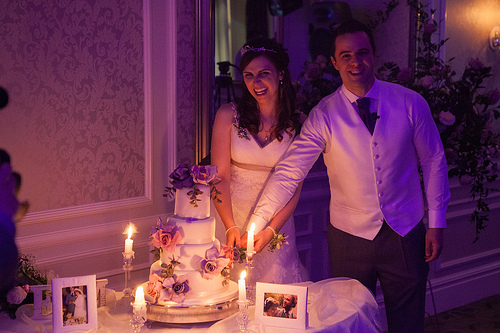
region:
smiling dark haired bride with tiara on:
[203, 30, 314, 290]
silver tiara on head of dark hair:
[234, 39, 289, 65]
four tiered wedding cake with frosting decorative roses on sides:
[127, 151, 244, 327]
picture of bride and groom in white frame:
[47, 269, 102, 331]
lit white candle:
[120, 218, 139, 252]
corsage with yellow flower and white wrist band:
[261, 220, 292, 255]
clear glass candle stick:
[111, 249, 138, 319]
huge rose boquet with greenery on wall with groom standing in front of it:
[299, 33, 499, 259]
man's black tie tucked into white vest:
[350, 92, 382, 137]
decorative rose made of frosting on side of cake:
[145, 213, 192, 257]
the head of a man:
[305, 20, 435, 90]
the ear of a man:
[315, 35, 352, 82]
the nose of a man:
[341, 50, 366, 75]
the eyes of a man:
[332, 26, 394, 77]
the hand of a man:
[403, 212, 452, 262]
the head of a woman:
[217, 28, 304, 116]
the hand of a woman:
[207, 210, 256, 250]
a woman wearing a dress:
[187, 0, 344, 275]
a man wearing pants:
[328, 189, 495, 299]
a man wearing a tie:
[336, 40, 437, 179]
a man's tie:
[355, 97, 375, 125]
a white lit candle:
[247, 223, 257, 252]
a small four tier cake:
[156, 172, 226, 293]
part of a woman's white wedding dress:
[222, 115, 303, 282]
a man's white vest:
[311, 83, 427, 240]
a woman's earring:
[280, 80, 285, 89]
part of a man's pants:
[320, 219, 434, 329]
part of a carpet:
[431, 296, 498, 328]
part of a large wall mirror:
[196, 0, 425, 174]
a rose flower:
[7, 283, 32, 307]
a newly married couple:
[98, 29, 498, 300]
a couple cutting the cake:
[146, 11, 347, 323]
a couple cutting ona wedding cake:
[122, 41, 409, 329]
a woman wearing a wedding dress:
[119, 43, 447, 329]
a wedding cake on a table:
[114, 141, 289, 331]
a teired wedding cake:
[121, 130, 196, 328]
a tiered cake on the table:
[128, 152, 303, 319]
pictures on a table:
[41, 200, 310, 330]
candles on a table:
[87, 158, 389, 330]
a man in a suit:
[290, 23, 499, 278]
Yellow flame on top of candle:
[121, 220, 136, 239]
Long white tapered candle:
[122, 237, 134, 255]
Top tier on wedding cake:
[174, 186, 212, 219]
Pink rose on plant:
[436, 107, 458, 127]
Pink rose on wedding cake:
[150, 222, 181, 245]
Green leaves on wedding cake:
[185, 186, 201, 206]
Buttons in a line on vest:
[365, 135, 385, 221]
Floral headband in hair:
[238, 43, 283, 55]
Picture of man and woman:
[263, 290, 298, 315]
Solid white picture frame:
[51, 277, 98, 327]